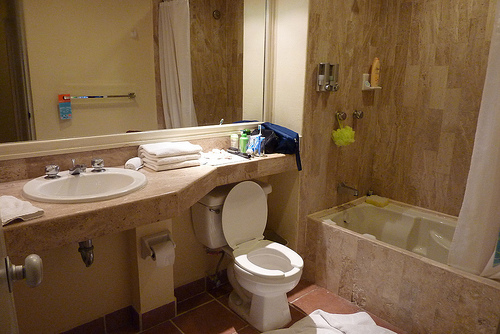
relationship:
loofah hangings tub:
[322, 82, 372, 160] [307, 167, 491, 306]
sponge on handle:
[333, 129, 353, 147] [337, 107, 348, 122]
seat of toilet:
[212, 180, 271, 248] [184, 181, 305, 321]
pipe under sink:
[78, 240, 95, 268] [21, 155, 149, 207]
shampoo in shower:
[364, 55, 389, 90] [320, 44, 497, 294]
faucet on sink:
[42, 156, 104, 178] [23, 168, 145, 203]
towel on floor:
[230, 305, 402, 331] [9, 249, 443, 332]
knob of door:
[2, 250, 59, 295] [4, 159, 41, 331]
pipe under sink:
[76, 233, 92, 273] [73, 244, 120, 281]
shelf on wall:
[347, 75, 379, 95] [390, 17, 468, 123]